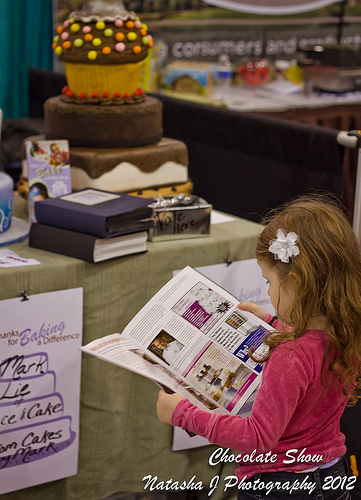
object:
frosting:
[50, 5, 152, 67]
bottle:
[217, 53, 230, 94]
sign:
[172, 257, 307, 450]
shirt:
[171, 326, 350, 484]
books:
[26, 222, 156, 264]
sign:
[171, 33, 356, 58]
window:
[141, 0, 361, 73]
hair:
[257, 194, 360, 404]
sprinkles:
[87, 50, 96, 58]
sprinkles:
[132, 46, 140, 53]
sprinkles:
[102, 47, 110, 53]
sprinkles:
[62, 41, 71, 49]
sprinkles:
[96, 22, 104, 28]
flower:
[268, 228, 300, 263]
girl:
[155, 191, 359, 500]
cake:
[24, 0, 189, 197]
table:
[0, 190, 272, 498]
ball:
[87, 50, 96, 60]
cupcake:
[51, 12, 152, 97]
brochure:
[78, 263, 281, 418]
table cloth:
[0, 186, 276, 497]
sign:
[0, 286, 81, 500]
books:
[33, 187, 155, 240]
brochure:
[23, 137, 73, 224]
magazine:
[80, 266, 283, 418]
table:
[141, 27, 361, 120]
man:
[147, 329, 185, 366]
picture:
[129, 280, 278, 417]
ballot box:
[136, 194, 212, 235]